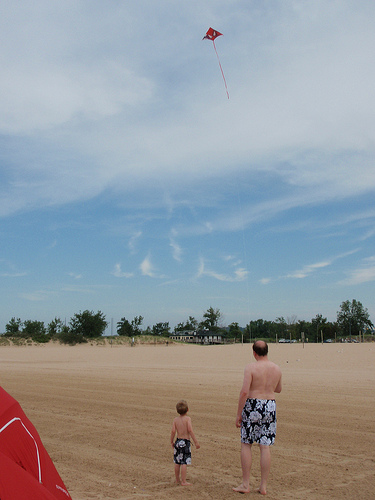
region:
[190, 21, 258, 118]
a kite in the sky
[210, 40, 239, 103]
a long red kite string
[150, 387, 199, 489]
a little boy watching the kite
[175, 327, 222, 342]
a large white beach house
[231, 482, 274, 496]
bare feet on sand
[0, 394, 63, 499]
a large red tent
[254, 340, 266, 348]
a bald spot on a head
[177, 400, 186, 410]
brown hair on a head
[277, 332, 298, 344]
car parked in a lot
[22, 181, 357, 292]
a bright blue sky with soft white clouds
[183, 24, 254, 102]
kite in the sky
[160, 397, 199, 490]
person wearing shorts on the beach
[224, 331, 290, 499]
man wearing flowered shorts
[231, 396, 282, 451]
pair of flowered shorts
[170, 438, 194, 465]
pair of flowered shorts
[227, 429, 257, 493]
leg of a man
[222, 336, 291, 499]
man on the beach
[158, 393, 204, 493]
child on the beach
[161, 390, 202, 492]
child with blonde hair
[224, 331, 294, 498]
man with bald spot on head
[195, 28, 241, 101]
a red kite in the sky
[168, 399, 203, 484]
a child standing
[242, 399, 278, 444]
the man is wearing black and white shorts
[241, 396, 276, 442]
man wearing shorts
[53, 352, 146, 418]
the sand is brown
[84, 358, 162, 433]
the sand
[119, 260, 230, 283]
the white clouds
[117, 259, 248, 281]
clouds in the sky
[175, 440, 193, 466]
the child is wearing shorts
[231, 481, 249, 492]
mans foot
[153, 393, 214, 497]
A small boy in a knee-length bathing suit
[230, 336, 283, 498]
An older man in a floral bathing suit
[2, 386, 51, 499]
A portion of a red tent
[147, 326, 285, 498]
A man and boy in matching floral bathing suits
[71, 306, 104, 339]
A bushy green tree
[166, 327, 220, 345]
A distant low building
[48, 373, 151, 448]
An area of smooth brown sand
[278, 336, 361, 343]
Several parked cars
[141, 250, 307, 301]
A sky with very wispy scattered clouds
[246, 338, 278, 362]
A man's partially bald head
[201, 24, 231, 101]
A red kite flying in the sky.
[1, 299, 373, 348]
A shoreline full of trees, shrubs and bushes.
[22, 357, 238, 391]
A sandy beach packed with moist sand.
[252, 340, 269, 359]
A man with a bald head.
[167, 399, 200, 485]
A kid wearing black and white swimming trunks.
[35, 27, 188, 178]
White clouds in a blue sky.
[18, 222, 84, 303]
A blue clear sky.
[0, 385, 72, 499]
A red tent on a beach.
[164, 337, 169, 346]
A man on the beach in the background.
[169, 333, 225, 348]
A house on a sandy beach.